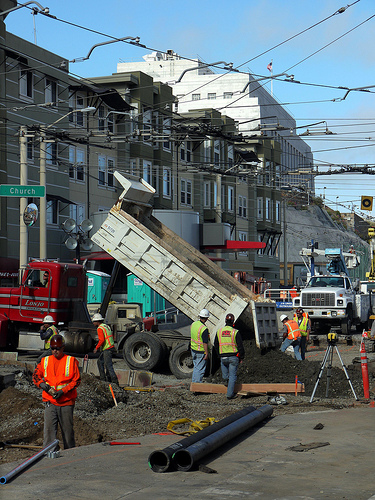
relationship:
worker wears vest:
[184, 303, 213, 393] [195, 305, 209, 319]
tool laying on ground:
[102, 439, 141, 447] [1, 406, 373, 498]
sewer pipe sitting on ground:
[146, 402, 208, 485] [215, 435, 343, 498]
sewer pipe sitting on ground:
[188, 412, 271, 457] [215, 435, 343, 498]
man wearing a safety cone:
[33, 328, 80, 363] [347, 337, 370, 373]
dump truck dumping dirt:
[99, 186, 272, 349] [221, 337, 332, 406]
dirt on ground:
[221, 337, 332, 406] [123, 377, 373, 479]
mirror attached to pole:
[19, 198, 43, 233] [7, 121, 37, 275]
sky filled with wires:
[161, 6, 263, 59] [232, 38, 343, 110]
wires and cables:
[232, 38, 343, 110] [81, 26, 356, 105]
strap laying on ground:
[160, 416, 211, 439] [119, 419, 215, 479]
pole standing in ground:
[350, 339, 373, 400] [290, 396, 373, 449]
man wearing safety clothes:
[31, 323, 88, 378] [40, 353, 82, 407]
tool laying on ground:
[105, 435, 141, 447] [75, 445, 179, 485]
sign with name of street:
[0, 178, 55, 205] [11, 251, 369, 498]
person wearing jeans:
[212, 310, 247, 343] [205, 349, 243, 397]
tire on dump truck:
[123, 328, 163, 377] [0, 170, 282, 378]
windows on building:
[29, 141, 139, 196] [11, 33, 301, 330]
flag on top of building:
[262, 57, 286, 76] [158, 45, 315, 304]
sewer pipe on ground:
[172, 404, 274, 472] [215, 435, 343, 498]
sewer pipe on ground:
[148, 406, 256, 472] [215, 435, 343, 498]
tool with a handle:
[102, 439, 141, 447] [107, 435, 147, 451]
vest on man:
[33, 357, 82, 395] [29, 328, 86, 375]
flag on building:
[266, 62, 272, 98] [136, 66, 286, 290]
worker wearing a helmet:
[189, 308, 209, 394] [196, 310, 210, 320]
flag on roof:
[266, 62, 272, 98] [221, 89, 259, 101]